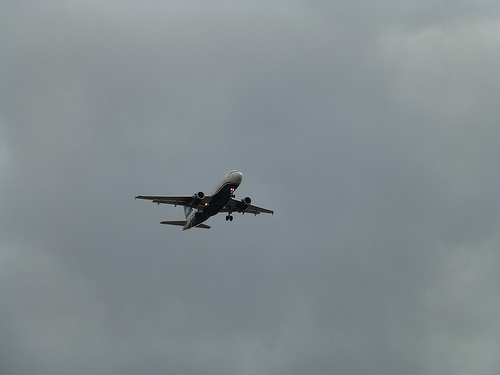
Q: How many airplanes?
A: One.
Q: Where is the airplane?
A: In the sky.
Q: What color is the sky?
A: Grey.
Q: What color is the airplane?
A: White.